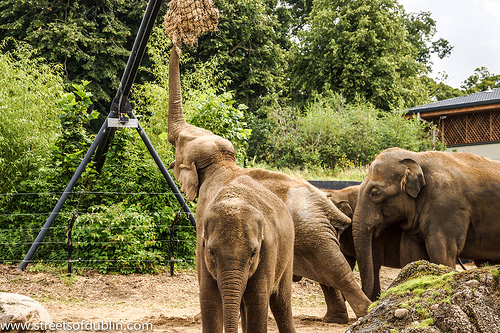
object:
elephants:
[166, 44, 500, 333]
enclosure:
[0, 0, 498, 331]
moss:
[348, 257, 500, 332]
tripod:
[14, 1, 198, 275]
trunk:
[167, 41, 185, 124]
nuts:
[160, 0, 218, 53]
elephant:
[195, 170, 296, 332]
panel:
[410, 105, 500, 148]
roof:
[398, 86, 500, 118]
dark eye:
[247, 246, 258, 263]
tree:
[1, 0, 173, 191]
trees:
[0, 0, 500, 158]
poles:
[68, 211, 81, 278]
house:
[398, 88, 500, 159]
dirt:
[0, 276, 392, 333]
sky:
[397, 1, 500, 91]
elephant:
[167, 45, 238, 201]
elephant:
[349, 142, 500, 302]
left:
[0, 1, 31, 332]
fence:
[0, 181, 196, 271]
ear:
[399, 158, 427, 200]